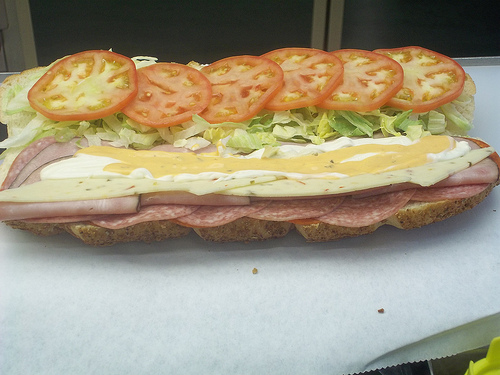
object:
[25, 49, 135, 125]
tomatoes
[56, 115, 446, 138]
lettuce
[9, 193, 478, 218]
ham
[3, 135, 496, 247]
bread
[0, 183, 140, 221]
pieces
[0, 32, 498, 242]
sandwich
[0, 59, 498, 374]
paper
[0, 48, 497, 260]
sub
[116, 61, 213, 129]
tomato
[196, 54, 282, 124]
tomato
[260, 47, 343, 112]
tomato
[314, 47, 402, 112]
tomato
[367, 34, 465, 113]
tomato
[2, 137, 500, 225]
meat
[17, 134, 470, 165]
sauce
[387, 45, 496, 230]
end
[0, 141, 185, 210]
piece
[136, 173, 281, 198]
piece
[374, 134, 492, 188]
piece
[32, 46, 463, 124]
row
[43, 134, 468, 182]
mustard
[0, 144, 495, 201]
cheese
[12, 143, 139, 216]
slice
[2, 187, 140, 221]
salami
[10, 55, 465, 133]
veggies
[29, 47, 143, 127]
slice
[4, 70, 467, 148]
salad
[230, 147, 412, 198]
piece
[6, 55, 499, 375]
table